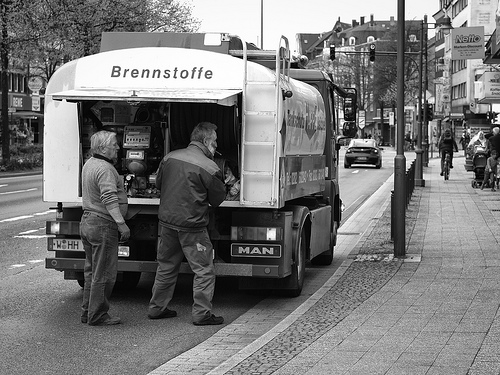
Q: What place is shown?
A: It is a road.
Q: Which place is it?
A: It is a road.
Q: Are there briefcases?
A: No, there are no briefcases.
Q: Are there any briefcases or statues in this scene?
A: No, there are no briefcases or statues.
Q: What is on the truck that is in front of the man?
A: The ladder is on the truck.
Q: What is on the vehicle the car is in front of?
A: The ladder is on the truck.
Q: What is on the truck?
A: The ladder is on the truck.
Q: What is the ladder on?
A: The ladder is on the truck.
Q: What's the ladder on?
A: The ladder is on the truck.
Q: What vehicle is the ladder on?
A: The ladder is on the truck.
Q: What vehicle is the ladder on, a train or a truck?
A: The ladder is on a truck.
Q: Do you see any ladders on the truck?
A: Yes, there is a ladder on the truck.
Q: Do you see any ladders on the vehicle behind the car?
A: Yes, there is a ladder on the truck.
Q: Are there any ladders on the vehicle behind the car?
A: Yes, there is a ladder on the truck.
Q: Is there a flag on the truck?
A: No, there is a ladder on the truck.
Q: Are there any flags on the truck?
A: No, there is a ladder on the truck.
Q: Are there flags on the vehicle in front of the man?
A: No, there is a ladder on the truck.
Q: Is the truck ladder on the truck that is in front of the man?
A: Yes, the ladder is on the truck.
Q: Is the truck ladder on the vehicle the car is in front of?
A: Yes, the ladder is on the truck.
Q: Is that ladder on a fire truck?
A: No, the ladder is on the truck.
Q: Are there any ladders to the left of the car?
A: Yes, there is a ladder to the left of the car.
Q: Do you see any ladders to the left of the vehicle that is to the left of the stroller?
A: Yes, there is a ladder to the left of the car.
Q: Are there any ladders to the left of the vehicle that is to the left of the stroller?
A: Yes, there is a ladder to the left of the car.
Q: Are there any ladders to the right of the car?
A: No, the ladder is to the left of the car.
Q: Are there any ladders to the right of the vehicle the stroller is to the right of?
A: No, the ladder is to the left of the car.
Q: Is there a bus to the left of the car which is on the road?
A: No, there is a ladder to the left of the car.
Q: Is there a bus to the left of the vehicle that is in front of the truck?
A: No, there is a ladder to the left of the car.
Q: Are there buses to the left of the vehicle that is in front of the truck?
A: No, there is a ladder to the left of the car.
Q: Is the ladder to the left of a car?
A: Yes, the ladder is to the left of a car.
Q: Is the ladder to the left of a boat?
A: No, the ladder is to the left of a car.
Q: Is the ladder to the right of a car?
A: No, the ladder is to the left of a car.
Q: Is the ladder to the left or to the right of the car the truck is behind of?
A: The ladder is to the left of the car.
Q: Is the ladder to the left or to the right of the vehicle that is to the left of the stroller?
A: The ladder is to the left of the car.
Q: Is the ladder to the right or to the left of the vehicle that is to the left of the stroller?
A: The ladder is to the left of the car.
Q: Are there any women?
A: Yes, there is a woman.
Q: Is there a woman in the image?
A: Yes, there is a woman.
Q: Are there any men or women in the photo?
A: Yes, there is a woman.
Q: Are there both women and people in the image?
A: Yes, there are both a woman and a person.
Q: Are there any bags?
A: No, there are no bags.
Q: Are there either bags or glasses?
A: No, there are no bags or glasses.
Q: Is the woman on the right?
A: Yes, the woman is on the right of the image.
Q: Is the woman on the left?
A: No, the woman is on the right of the image.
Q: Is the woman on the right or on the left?
A: The woman is on the right of the image.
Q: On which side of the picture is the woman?
A: The woman is on the right of the image.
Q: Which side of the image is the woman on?
A: The woman is on the right of the image.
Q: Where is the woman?
A: The woman is on the sidewalk.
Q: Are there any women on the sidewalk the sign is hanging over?
A: Yes, there is a woman on the sidewalk.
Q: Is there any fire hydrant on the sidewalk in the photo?
A: No, there is a woman on the sidewalk.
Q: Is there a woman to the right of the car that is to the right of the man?
A: Yes, there is a woman to the right of the car.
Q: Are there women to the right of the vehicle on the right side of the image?
A: Yes, there is a woman to the right of the car.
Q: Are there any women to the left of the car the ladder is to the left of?
A: No, the woman is to the right of the car.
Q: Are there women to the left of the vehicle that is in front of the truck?
A: No, the woman is to the right of the car.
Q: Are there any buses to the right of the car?
A: No, there is a woman to the right of the car.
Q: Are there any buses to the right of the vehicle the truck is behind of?
A: No, there is a woman to the right of the car.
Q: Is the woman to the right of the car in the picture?
A: Yes, the woman is to the right of the car.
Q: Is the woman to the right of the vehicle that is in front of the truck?
A: Yes, the woman is to the right of the car.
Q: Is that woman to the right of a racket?
A: No, the woman is to the right of the car.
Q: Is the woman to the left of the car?
A: No, the woman is to the right of the car.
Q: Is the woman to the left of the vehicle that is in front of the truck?
A: No, the woman is to the right of the car.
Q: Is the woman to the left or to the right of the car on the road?
A: The woman is to the right of the car.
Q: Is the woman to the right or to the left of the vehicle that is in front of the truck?
A: The woman is to the right of the car.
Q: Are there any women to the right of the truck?
A: Yes, there is a woman to the right of the truck.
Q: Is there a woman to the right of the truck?
A: Yes, there is a woman to the right of the truck.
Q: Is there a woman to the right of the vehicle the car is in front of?
A: Yes, there is a woman to the right of the truck.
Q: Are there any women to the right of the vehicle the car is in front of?
A: Yes, there is a woman to the right of the truck.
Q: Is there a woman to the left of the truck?
A: No, the woman is to the right of the truck.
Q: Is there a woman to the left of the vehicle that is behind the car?
A: No, the woman is to the right of the truck.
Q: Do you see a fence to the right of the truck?
A: No, there is a woman to the right of the truck.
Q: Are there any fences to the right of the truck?
A: No, there is a woman to the right of the truck.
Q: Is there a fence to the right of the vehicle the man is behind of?
A: No, there is a woman to the right of the truck.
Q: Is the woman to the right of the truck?
A: Yes, the woman is to the right of the truck.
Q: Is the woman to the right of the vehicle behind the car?
A: Yes, the woman is to the right of the truck.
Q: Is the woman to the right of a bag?
A: No, the woman is to the right of the truck.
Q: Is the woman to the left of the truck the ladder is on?
A: No, the woman is to the right of the truck.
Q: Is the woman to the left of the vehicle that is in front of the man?
A: No, the woman is to the right of the truck.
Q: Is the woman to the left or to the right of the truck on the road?
A: The woman is to the right of the truck.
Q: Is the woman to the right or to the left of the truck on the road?
A: The woman is to the right of the truck.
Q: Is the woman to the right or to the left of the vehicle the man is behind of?
A: The woman is to the right of the truck.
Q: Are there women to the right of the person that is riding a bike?
A: Yes, there is a woman to the right of the person.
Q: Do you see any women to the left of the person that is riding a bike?
A: No, the woman is to the right of the person.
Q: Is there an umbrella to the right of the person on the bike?
A: No, there is a woman to the right of the person.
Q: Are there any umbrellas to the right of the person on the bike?
A: No, there is a woman to the right of the person.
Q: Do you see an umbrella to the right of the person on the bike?
A: No, there is a woman to the right of the person.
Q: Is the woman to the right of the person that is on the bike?
A: Yes, the woman is to the right of the person.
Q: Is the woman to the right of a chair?
A: No, the woman is to the right of the person.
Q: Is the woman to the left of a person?
A: No, the woman is to the right of a person.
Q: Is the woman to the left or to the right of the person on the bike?
A: The woman is to the right of the person.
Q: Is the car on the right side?
A: Yes, the car is on the right of the image.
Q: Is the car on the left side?
A: No, the car is on the right of the image.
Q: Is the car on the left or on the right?
A: The car is on the right of the image.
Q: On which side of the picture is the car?
A: The car is on the right of the image.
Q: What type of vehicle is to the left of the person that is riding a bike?
A: The vehicle is a car.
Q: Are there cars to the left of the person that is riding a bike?
A: Yes, there is a car to the left of the person.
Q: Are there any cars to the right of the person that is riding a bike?
A: No, the car is to the left of the person.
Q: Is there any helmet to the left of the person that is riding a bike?
A: No, there is a car to the left of the person.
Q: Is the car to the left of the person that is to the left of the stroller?
A: Yes, the car is to the left of the person.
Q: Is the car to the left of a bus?
A: No, the car is to the left of the person.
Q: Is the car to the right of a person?
A: No, the car is to the left of a person.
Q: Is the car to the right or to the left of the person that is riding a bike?
A: The car is to the left of the person.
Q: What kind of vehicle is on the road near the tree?
A: The vehicle is a car.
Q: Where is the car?
A: The car is on the road.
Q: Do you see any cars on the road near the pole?
A: Yes, there is a car on the road.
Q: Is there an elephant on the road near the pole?
A: No, there is a car on the road.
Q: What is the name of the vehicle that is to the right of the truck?
A: The vehicle is a car.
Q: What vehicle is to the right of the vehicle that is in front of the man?
A: The vehicle is a car.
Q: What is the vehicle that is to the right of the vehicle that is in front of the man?
A: The vehicle is a car.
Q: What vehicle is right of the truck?
A: The vehicle is a car.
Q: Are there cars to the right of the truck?
A: Yes, there is a car to the right of the truck.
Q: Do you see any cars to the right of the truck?
A: Yes, there is a car to the right of the truck.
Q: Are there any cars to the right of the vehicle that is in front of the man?
A: Yes, there is a car to the right of the truck.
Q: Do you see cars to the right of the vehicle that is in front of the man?
A: Yes, there is a car to the right of the truck.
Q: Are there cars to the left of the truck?
A: No, the car is to the right of the truck.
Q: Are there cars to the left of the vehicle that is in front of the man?
A: No, the car is to the right of the truck.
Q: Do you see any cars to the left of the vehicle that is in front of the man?
A: No, the car is to the right of the truck.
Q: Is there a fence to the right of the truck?
A: No, there is a car to the right of the truck.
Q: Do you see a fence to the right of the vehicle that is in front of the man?
A: No, there is a car to the right of the truck.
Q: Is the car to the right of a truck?
A: Yes, the car is to the right of a truck.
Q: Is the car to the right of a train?
A: No, the car is to the right of a truck.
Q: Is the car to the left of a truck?
A: No, the car is to the right of a truck.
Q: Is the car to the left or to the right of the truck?
A: The car is to the right of the truck.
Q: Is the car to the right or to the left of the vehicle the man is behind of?
A: The car is to the right of the truck.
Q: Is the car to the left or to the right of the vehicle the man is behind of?
A: The car is to the right of the truck.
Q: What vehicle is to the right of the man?
A: The vehicle is a car.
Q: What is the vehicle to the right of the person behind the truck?
A: The vehicle is a car.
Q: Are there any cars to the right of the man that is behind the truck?
A: Yes, there is a car to the right of the man.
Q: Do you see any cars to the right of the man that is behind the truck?
A: Yes, there is a car to the right of the man.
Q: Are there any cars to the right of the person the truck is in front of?
A: Yes, there is a car to the right of the man.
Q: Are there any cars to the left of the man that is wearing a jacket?
A: No, the car is to the right of the man.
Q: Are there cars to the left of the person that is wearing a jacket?
A: No, the car is to the right of the man.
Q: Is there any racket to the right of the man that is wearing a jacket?
A: No, there is a car to the right of the man.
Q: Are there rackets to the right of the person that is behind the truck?
A: No, there is a car to the right of the man.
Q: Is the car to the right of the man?
A: Yes, the car is to the right of the man.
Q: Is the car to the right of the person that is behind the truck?
A: Yes, the car is to the right of the man.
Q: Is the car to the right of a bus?
A: No, the car is to the right of the man.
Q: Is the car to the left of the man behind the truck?
A: No, the car is to the right of the man.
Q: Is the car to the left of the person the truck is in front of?
A: No, the car is to the right of the man.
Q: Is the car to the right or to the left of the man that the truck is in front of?
A: The car is to the right of the man.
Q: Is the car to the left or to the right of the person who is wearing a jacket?
A: The car is to the right of the man.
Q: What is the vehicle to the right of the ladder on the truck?
A: The vehicle is a car.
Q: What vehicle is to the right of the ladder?
A: The vehicle is a car.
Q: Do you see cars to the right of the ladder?
A: Yes, there is a car to the right of the ladder.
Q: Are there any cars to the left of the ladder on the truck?
A: No, the car is to the right of the ladder.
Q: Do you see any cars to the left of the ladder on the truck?
A: No, the car is to the right of the ladder.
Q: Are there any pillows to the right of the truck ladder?
A: No, there is a car to the right of the ladder.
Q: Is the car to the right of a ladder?
A: Yes, the car is to the right of a ladder.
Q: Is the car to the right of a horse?
A: No, the car is to the right of a ladder.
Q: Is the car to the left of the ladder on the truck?
A: No, the car is to the right of the ladder.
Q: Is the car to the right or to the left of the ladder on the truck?
A: The car is to the right of the ladder.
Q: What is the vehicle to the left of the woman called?
A: The vehicle is a car.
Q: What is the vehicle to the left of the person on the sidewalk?
A: The vehicle is a car.